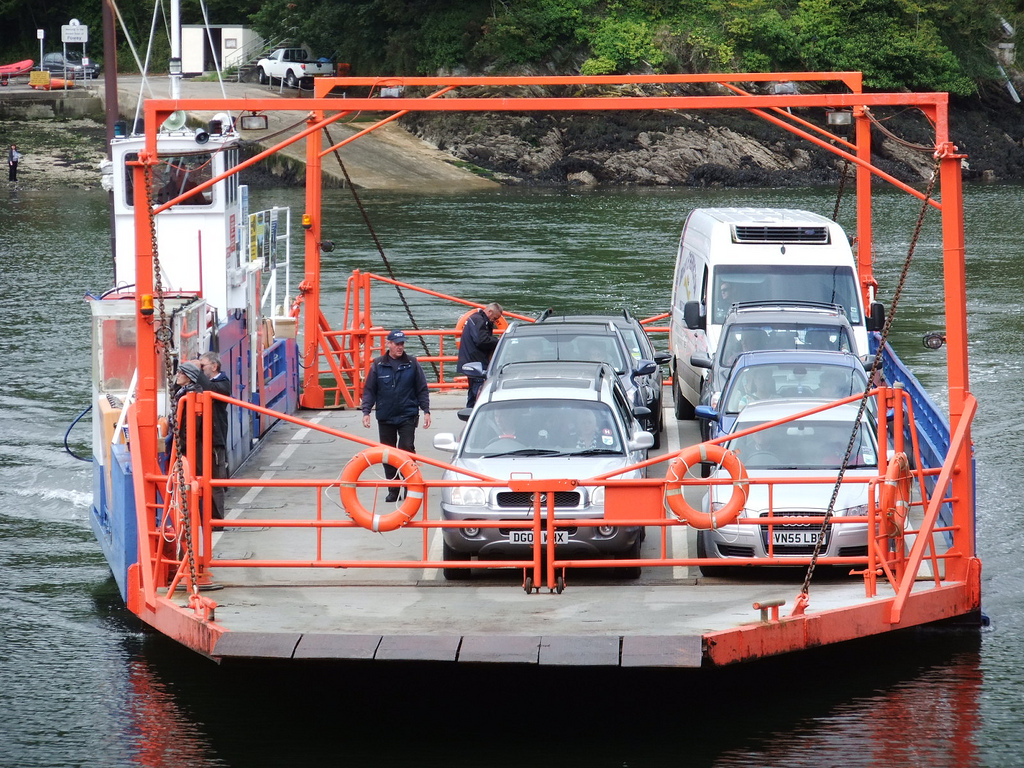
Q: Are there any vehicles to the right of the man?
A: Yes, there are vehicles to the right of the man.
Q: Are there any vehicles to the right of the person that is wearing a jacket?
A: Yes, there are vehicles to the right of the man.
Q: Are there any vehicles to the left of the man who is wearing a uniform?
A: No, the vehicles are to the right of the man.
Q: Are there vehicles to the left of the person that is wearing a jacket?
A: No, the vehicles are to the right of the man.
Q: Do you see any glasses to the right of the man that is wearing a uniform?
A: No, there are vehicles to the right of the man.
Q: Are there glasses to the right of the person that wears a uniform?
A: No, there are vehicles to the right of the man.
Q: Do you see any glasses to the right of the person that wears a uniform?
A: No, there are vehicles to the right of the man.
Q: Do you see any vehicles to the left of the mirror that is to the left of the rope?
A: Yes, there are vehicles to the left of the mirror.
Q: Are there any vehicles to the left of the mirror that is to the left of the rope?
A: Yes, there are vehicles to the left of the mirror.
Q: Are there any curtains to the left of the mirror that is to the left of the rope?
A: No, there are vehicles to the left of the mirror.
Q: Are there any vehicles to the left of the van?
A: Yes, there are vehicles to the left of the van.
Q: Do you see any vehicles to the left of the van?
A: Yes, there are vehicles to the left of the van.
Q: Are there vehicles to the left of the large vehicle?
A: Yes, there are vehicles to the left of the van.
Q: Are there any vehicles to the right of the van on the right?
A: No, the vehicles are to the left of the van.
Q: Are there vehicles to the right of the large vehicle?
A: No, the vehicles are to the left of the van.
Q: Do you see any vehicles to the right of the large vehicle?
A: No, the vehicles are to the left of the van.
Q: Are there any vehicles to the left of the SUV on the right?
A: Yes, there are vehicles to the left of the SUV.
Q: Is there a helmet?
A: No, there are no helmets.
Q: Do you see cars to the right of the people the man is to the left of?
A: Yes, there is a car to the right of the people.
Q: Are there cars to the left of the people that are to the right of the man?
A: No, the car is to the right of the people.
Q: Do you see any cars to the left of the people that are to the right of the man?
A: No, the car is to the right of the people.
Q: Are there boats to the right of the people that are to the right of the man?
A: No, there is a car to the right of the people.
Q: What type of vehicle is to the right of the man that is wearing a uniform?
A: The vehicle is a car.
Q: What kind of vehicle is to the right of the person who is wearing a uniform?
A: The vehicle is a car.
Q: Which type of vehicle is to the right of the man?
A: The vehicle is a car.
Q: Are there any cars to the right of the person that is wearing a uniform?
A: Yes, there is a car to the right of the man.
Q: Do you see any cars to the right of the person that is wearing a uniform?
A: Yes, there is a car to the right of the man.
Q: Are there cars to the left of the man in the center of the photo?
A: No, the car is to the right of the man.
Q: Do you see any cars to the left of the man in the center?
A: No, the car is to the right of the man.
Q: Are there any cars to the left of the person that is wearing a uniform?
A: No, the car is to the right of the man.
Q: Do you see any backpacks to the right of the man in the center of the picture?
A: No, there is a car to the right of the man.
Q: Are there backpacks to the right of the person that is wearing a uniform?
A: No, there is a car to the right of the man.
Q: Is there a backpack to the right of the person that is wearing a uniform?
A: No, there is a car to the right of the man.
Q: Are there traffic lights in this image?
A: No, there are no traffic lights.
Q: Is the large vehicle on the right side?
A: Yes, the van is on the right of the image.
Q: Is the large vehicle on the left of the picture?
A: No, the van is on the right of the image.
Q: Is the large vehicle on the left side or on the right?
A: The van is on the right of the image.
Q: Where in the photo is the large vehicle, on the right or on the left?
A: The van is on the right of the image.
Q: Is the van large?
A: Yes, the van is large.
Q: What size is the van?
A: The van is large.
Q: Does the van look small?
A: No, the van is large.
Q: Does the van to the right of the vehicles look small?
A: No, the van is large.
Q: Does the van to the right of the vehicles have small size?
A: No, the van is large.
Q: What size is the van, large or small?
A: The van is large.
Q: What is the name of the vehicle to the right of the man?
A: The vehicle is a van.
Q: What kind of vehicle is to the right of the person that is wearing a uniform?
A: The vehicle is a van.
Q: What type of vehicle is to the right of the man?
A: The vehicle is a van.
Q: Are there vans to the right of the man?
A: Yes, there is a van to the right of the man.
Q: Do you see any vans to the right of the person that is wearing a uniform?
A: Yes, there is a van to the right of the man.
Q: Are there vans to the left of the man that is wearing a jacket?
A: No, the van is to the right of the man.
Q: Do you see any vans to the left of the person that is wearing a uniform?
A: No, the van is to the right of the man.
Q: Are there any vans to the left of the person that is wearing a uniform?
A: No, the van is to the right of the man.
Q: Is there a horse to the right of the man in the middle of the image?
A: No, there is a van to the right of the man.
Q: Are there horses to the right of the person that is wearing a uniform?
A: No, there is a van to the right of the man.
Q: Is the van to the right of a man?
A: Yes, the van is to the right of a man.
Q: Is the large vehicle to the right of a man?
A: Yes, the van is to the right of a man.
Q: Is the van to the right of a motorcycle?
A: No, the van is to the right of a man.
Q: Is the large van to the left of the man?
A: No, the van is to the right of the man.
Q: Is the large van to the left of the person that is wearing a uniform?
A: No, the van is to the right of the man.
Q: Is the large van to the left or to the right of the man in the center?
A: The van is to the right of the man.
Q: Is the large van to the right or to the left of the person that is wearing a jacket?
A: The van is to the right of the man.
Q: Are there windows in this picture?
A: Yes, there is a window.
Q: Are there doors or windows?
A: Yes, there is a window.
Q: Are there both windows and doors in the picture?
A: Yes, there are both a window and a door.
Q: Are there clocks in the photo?
A: No, there are no clocks.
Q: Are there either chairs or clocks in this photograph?
A: No, there are no clocks or chairs.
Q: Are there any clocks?
A: No, there are no clocks.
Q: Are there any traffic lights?
A: No, there are no traffic lights.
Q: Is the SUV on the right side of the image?
A: Yes, the SUV is on the right of the image.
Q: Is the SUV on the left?
A: No, the SUV is on the right of the image.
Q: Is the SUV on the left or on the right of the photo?
A: The SUV is on the right of the image.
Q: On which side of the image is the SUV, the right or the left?
A: The SUV is on the right of the image.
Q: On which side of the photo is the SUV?
A: The SUV is on the right of the image.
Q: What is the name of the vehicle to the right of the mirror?
A: The vehicle is a SUV.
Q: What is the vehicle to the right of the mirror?
A: The vehicle is a SUV.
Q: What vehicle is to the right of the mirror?
A: The vehicle is a SUV.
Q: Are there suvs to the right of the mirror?
A: Yes, there is a SUV to the right of the mirror.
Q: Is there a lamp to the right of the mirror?
A: No, there is a SUV to the right of the mirror.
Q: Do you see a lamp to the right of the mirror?
A: No, there is a SUV to the right of the mirror.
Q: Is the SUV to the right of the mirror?
A: Yes, the SUV is to the right of the mirror.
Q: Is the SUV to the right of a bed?
A: No, the SUV is to the right of the mirror.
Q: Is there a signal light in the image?
A: No, there are no traffic lights.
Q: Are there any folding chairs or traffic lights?
A: No, there are no traffic lights or folding chairs.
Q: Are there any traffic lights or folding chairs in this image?
A: No, there are no traffic lights or folding chairs.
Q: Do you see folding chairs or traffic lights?
A: No, there are no traffic lights or folding chairs.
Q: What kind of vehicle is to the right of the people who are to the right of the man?
A: The vehicle is a car.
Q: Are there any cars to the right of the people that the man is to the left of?
A: Yes, there is a car to the right of the people.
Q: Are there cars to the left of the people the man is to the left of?
A: No, the car is to the right of the people.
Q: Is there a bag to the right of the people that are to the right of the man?
A: No, there is a car to the right of the people.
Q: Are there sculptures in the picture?
A: No, there are no sculptures.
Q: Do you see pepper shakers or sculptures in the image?
A: No, there are no sculptures or pepper shakers.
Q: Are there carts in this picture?
A: No, there are no carts.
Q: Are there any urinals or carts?
A: No, there are no carts or urinals.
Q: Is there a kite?
A: No, there are no kites.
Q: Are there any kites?
A: No, there are no kites.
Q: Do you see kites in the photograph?
A: No, there are no kites.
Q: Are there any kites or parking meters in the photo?
A: No, there are no kites or parking meters.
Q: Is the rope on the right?
A: Yes, the rope is on the right of the image.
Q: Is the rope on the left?
A: No, the rope is on the right of the image.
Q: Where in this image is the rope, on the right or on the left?
A: The rope is on the right of the image.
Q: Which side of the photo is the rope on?
A: The rope is on the right of the image.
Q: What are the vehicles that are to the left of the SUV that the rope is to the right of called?
A: The vehicles are cars.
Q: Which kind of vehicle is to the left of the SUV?
A: The vehicles are cars.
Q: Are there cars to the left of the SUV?
A: Yes, there are cars to the left of the SUV.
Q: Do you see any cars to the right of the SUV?
A: No, the cars are to the left of the SUV.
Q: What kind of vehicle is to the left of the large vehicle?
A: The vehicles are cars.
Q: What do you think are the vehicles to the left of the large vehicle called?
A: The vehicles are cars.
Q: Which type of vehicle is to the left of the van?
A: The vehicles are cars.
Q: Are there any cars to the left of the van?
A: Yes, there are cars to the left of the van.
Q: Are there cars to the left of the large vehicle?
A: Yes, there are cars to the left of the van.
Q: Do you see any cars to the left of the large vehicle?
A: Yes, there are cars to the left of the van.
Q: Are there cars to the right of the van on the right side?
A: No, the cars are to the left of the van.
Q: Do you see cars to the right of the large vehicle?
A: No, the cars are to the left of the van.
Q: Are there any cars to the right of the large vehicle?
A: No, the cars are to the left of the van.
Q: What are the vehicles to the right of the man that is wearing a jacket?
A: The vehicles are cars.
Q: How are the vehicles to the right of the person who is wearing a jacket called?
A: The vehicles are cars.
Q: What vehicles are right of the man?
A: The vehicles are cars.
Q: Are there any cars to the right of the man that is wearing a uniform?
A: Yes, there are cars to the right of the man.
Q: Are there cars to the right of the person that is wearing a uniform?
A: Yes, there are cars to the right of the man.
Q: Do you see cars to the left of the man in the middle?
A: No, the cars are to the right of the man.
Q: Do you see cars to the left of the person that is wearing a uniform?
A: No, the cars are to the right of the man.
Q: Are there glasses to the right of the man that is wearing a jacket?
A: No, there are cars to the right of the man.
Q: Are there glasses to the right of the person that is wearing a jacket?
A: No, there are cars to the right of the man.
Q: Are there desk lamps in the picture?
A: No, there are no desk lamps.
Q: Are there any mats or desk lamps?
A: No, there are no desk lamps or mats.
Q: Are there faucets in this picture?
A: No, there are no faucets.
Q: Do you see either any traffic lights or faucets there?
A: No, there are no faucets or traffic lights.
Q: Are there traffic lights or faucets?
A: No, there are no faucets or traffic lights.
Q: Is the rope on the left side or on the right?
A: The rope is on the right of the image.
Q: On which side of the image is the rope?
A: The rope is on the right of the image.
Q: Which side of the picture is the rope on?
A: The rope is on the right of the image.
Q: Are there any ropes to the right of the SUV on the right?
A: Yes, there is a rope to the right of the SUV.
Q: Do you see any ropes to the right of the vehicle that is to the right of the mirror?
A: Yes, there is a rope to the right of the SUV.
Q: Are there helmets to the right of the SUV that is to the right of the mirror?
A: No, there is a rope to the right of the SUV.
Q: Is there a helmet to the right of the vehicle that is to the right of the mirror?
A: No, there is a rope to the right of the SUV.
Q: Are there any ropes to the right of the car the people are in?
A: Yes, there is a rope to the right of the car.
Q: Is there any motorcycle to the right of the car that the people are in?
A: No, there is a rope to the right of the car.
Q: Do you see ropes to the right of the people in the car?
A: Yes, there is a rope to the right of the people.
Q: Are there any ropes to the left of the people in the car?
A: No, the rope is to the right of the people.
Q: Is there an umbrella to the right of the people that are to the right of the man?
A: No, there is a rope to the right of the people.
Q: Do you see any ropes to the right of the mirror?
A: Yes, there is a rope to the right of the mirror.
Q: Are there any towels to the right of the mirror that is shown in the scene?
A: No, there is a rope to the right of the mirror.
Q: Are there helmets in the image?
A: No, there are no helmets.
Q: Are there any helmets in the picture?
A: No, there are no helmets.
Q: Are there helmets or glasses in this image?
A: No, there are no helmets or glasses.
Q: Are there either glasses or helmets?
A: No, there are no helmets or glasses.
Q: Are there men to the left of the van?
A: Yes, there is a man to the left of the van.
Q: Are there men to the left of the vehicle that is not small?
A: Yes, there is a man to the left of the van.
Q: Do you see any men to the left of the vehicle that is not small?
A: Yes, there is a man to the left of the van.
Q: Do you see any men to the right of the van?
A: No, the man is to the left of the van.